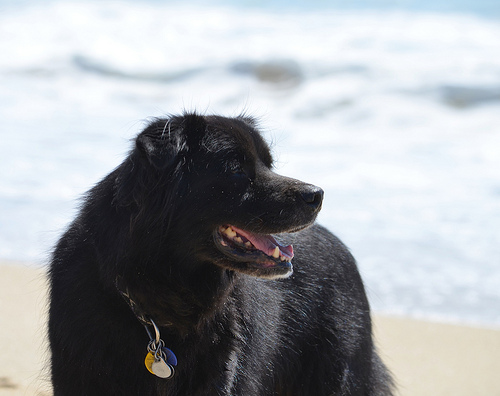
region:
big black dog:
[15, 108, 370, 382]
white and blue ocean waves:
[35, 21, 102, 78]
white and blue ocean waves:
[404, 33, 429, 70]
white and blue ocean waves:
[402, 96, 432, 128]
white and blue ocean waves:
[350, 128, 414, 186]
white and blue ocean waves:
[25, 63, 100, 138]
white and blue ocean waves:
[164, 32, 235, 84]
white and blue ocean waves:
[1, 95, 66, 155]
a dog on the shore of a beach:
[26, 33, 427, 389]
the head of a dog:
[126, 103, 335, 293]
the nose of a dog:
[272, 164, 337, 228]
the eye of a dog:
[218, 150, 249, 180]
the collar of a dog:
[106, 256, 220, 377]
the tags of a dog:
[136, 329, 186, 382]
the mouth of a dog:
[212, 209, 313, 274]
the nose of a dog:
[299, 181, 326, 210]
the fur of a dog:
[238, 298, 352, 376]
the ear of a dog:
[134, 110, 186, 176]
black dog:
[25, 102, 382, 380]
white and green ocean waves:
[374, 58, 411, 106]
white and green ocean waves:
[377, 111, 475, 213]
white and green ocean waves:
[392, 152, 444, 240]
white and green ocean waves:
[375, 206, 435, 296]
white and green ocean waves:
[278, 22, 369, 103]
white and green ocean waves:
[310, 63, 395, 153]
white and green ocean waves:
[140, 12, 244, 73]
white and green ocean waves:
[8, 22, 126, 89]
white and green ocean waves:
[22, 62, 62, 106]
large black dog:
[30, 109, 421, 394]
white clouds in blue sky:
[390, 8, 458, 50]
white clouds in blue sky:
[331, 11, 371, 36]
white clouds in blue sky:
[374, 13, 451, 73]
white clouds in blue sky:
[272, 22, 342, 66]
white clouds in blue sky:
[207, 21, 274, 68]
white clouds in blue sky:
[70, 11, 125, 49]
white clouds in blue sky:
[42, 6, 113, 70]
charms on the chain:
[140, 338, 184, 380]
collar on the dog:
[100, 270, 154, 325]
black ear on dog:
[141, 124, 187, 166]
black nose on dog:
[291, 180, 325, 202]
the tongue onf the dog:
[237, 224, 293, 257]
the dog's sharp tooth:
[273, 244, 281, 259]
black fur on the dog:
[232, 276, 356, 390]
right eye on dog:
[221, 154, 248, 174]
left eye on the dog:
[261, 158, 275, 170]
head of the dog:
[78, 107, 328, 300]